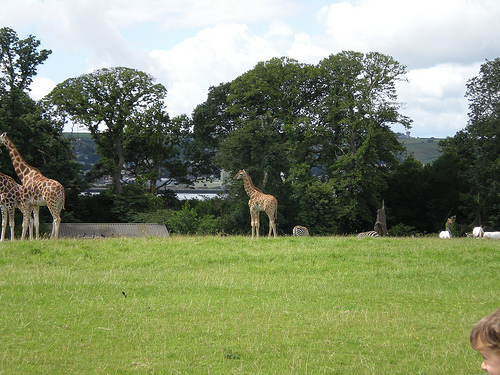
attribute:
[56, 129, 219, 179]
roof — grey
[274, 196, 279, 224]
tail — long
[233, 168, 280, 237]
giraffe — tall, brown, tan , spotted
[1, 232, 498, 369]
field — flat, grassy, green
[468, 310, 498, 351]
hair — brown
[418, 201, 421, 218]
ground — brown, tan, spotted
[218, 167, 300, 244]
giraffe — looking left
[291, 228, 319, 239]
zebra — black and white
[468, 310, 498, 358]
hair — blonde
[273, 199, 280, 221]
tail — long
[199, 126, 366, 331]
giraffe — tall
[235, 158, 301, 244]
giraffe — standing